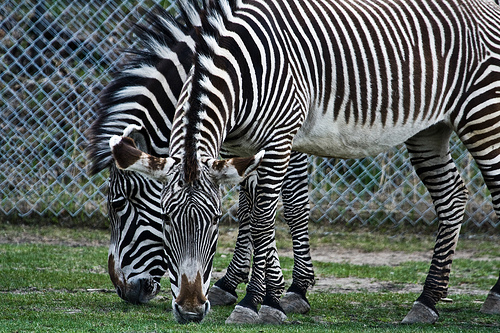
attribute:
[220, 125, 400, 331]
legs — fore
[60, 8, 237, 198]
mane — white , black 